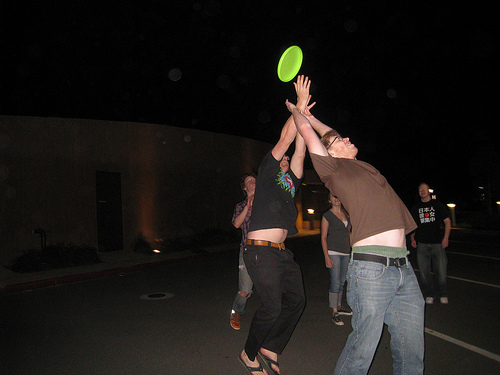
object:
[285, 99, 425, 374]
man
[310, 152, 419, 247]
shirt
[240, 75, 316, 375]
man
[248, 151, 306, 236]
shirt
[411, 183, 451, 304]
man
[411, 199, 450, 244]
shirt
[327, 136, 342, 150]
glasses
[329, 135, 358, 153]
face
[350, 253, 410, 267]
belt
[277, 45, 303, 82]
frisbee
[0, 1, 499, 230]
air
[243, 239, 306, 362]
pants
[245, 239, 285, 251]
belt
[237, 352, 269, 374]
flip flops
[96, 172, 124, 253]
door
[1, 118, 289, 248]
building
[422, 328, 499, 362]
lines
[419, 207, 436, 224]
writing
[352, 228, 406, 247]
belly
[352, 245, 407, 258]
underwear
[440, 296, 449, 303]
sneakers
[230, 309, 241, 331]
shoe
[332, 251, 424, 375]
jeans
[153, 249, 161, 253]
light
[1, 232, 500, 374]
ground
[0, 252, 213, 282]
sidewalk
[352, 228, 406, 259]
waist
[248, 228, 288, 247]
waist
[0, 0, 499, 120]
sky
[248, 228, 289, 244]
belly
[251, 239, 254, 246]
loops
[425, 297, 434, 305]
feet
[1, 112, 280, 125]
roof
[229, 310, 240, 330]
foot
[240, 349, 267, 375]
foot